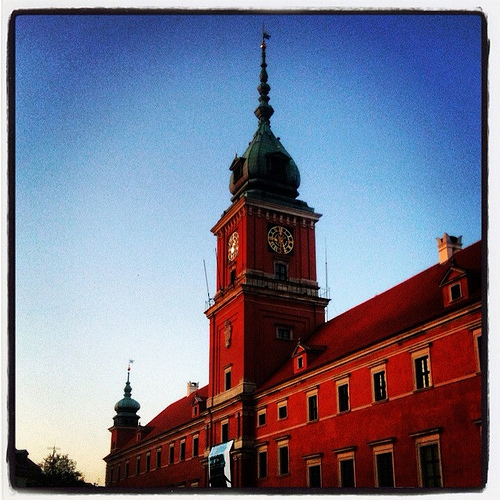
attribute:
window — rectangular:
[299, 377, 325, 427]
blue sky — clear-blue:
[2, 0, 479, 487]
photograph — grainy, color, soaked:
[18, 14, 483, 485]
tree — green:
[33, 445, 101, 492]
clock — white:
[256, 226, 301, 260]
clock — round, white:
[246, 210, 356, 271]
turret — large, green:
[249, 18, 281, 132]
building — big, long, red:
[92, 20, 492, 490]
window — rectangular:
[331, 452, 358, 489]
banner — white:
[197, 424, 257, 472]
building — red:
[183, 301, 421, 479]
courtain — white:
[415, 356, 430, 386]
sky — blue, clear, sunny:
[323, 37, 423, 130]